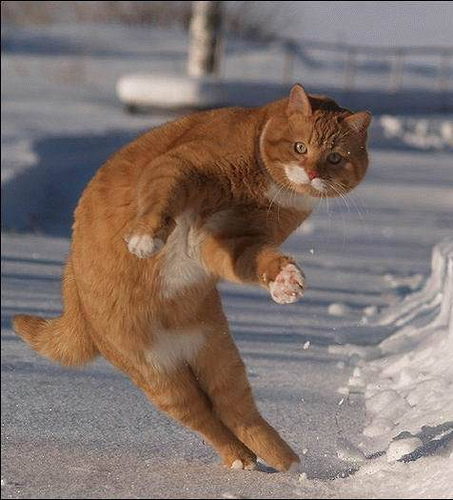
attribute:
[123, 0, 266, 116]
ship — black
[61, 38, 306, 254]
back — arched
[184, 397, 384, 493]
feet — clutched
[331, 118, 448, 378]
snow — here, white, dirty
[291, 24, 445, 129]
bridge — here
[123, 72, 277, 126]
object — here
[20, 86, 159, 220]
shadow — here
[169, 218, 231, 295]
patch — white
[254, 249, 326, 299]
paws — brown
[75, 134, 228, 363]
body — brown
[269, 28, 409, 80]
fence — here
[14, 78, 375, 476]
cat — tan